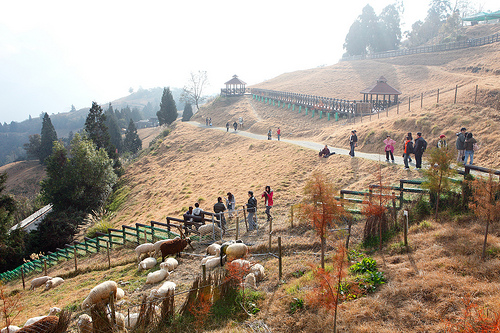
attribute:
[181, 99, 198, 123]
tree — green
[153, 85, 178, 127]
tree — green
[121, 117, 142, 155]
tree — green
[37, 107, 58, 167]
tree — green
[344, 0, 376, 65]
tree — green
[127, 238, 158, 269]
sheep — white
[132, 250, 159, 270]
sheep — white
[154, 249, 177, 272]
sheep — white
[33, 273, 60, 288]
sheep — white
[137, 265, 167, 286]
sheep — white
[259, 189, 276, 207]
jacket — red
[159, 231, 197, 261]
sheep — brown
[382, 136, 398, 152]
jacket — pink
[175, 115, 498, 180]
sidewalk — gray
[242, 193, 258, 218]
jacket — black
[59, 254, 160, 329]
sheep — fenced in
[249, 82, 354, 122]
walkway — raised, connecting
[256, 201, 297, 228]
jacket — red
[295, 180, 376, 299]
tree — orange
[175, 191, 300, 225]
people — walking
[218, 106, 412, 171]
road — narrow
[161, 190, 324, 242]
people — grouped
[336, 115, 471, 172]
people — grouped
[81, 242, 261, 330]
sheep — grouped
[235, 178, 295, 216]
girl — standing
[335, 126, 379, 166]
man — walking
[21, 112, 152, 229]
trees — grouped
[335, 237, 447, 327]
grass — green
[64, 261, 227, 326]
sheep — eating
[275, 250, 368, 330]
trees — red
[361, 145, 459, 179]
people — standing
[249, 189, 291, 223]
shirt — red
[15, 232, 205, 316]
stairs — green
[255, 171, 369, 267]
tree — sparse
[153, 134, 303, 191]
grass — yellow